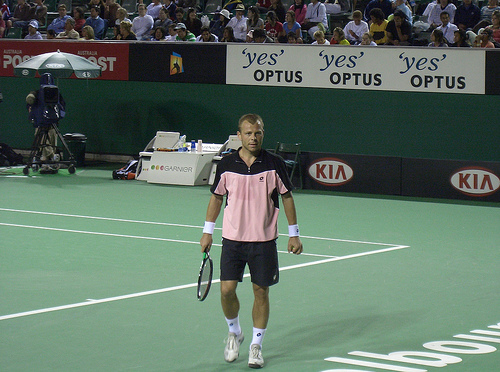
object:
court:
[1, 164, 500, 371]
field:
[0, 162, 499, 372]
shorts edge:
[249, 280, 281, 290]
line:
[0, 219, 340, 259]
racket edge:
[206, 256, 213, 293]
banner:
[300, 148, 401, 196]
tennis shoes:
[222, 329, 246, 364]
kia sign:
[447, 168, 499, 197]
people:
[22, 20, 44, 42]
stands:
[0, 1, 499, 204]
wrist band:
[199, 220, 218, 234]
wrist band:
[286, 224, 299, 237]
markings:
[0, 246, 411, 319]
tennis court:
[1, 162, 500, 372]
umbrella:
[11, 49, 107, 78]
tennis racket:
[196, 248, 214, 301]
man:
[196, 111, 303, 370]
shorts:
[218, 237, 281, 286]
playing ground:
[0, 164, 499, 371]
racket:
[197, 244, 214, 303]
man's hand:
[197, 233, 213, 254]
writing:
[321, 321, 500, 371]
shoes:
[245, 343, 265, 370]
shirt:
[210, 145, 297, 245]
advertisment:
[306, 159, 354, 187]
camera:
[28, 83, 68, 127]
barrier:
[0, 76, 499, 164]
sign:
[170, 50, 184, 74]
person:
[26, 71, 61, 174]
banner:
[224, 41, 485, 96]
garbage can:
[61, 132, 88, 167]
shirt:
[368, 18, 390, 46]